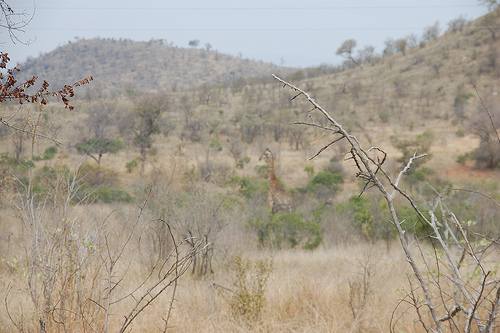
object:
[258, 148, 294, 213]
giraffe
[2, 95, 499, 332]
field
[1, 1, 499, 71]
sky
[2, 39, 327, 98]
hill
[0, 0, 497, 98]
background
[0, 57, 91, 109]
tree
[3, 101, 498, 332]
grass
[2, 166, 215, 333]
bush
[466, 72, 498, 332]
plant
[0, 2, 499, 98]
distance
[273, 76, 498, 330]
twig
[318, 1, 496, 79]
mound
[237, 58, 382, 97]
valley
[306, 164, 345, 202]
shrub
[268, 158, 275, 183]
neck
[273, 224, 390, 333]
branch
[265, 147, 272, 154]
ear